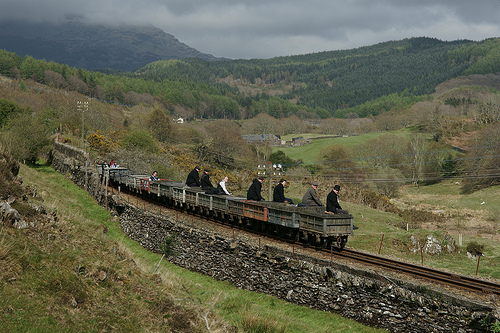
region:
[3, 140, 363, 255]
a train with people riding on it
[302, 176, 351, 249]
two men wearing coats riding on a train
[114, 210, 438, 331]
rocks to hold hillside up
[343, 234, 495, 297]
train track in field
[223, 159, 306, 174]
lights out in the field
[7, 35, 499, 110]
green mountain range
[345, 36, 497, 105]
a grassy hillside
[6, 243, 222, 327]
grassy and rocky hillside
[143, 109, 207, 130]
a white house in the background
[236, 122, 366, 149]
building in the distance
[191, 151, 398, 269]
people riding on rails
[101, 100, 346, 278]
people riding on rails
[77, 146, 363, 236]
SMALL TRAIN OF CARTS WITH PEOPLE ATOP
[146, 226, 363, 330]
BRICK WALL UNDER TRACKS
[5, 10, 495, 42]
DARK CLOUDS COMING IN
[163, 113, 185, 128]
SMALL WHITE BUILDING IN THE DISTANCE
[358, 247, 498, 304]
IRON RAILROAD TRACKS ON GROUND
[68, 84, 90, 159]
TALL WOODEN LIGHT POLE BY TRACKS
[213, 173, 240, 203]
WHITE SLEEVES ON PASSENGER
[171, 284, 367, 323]
GREEN GRASS ON GROUND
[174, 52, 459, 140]
FAR OFF TREES ON ROLLING HILLS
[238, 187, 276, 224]
ORANGE CART ON TRAIN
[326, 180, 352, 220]
person sitting on box car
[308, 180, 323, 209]
person sitting on box car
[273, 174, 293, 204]
person sitting on box car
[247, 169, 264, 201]
person sitting on box car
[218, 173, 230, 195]
person sitting on box car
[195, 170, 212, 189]
person sitting on box car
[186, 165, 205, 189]
person sitting on box car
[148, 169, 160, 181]
person sitting on box car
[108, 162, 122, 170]
person sitting on box car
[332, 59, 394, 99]
trees on the ground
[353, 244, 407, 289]
tracks below the train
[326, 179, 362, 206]
person with a hat on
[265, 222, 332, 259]
wheels on the train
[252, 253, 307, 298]
rocks next to tracks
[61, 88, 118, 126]
lights on the ground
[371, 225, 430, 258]
fence next to the people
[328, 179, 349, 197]
hat on a person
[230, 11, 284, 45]
clouds in the sky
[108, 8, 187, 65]
hill in the background